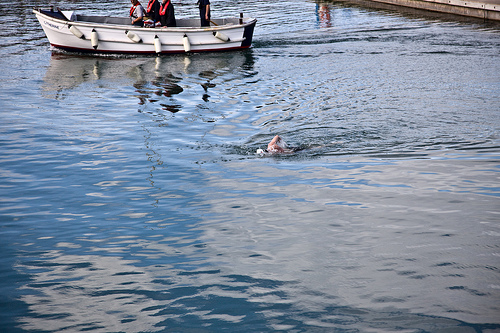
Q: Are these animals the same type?
A: Yes, all the animals are zebras.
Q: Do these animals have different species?
A: No, all the animals are zebras.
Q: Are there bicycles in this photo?
A: No, there are no bicycles.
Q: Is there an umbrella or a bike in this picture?
A: No, there are no bikes or umbrellas.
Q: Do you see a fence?
A: No, there are no fences.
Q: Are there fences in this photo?
A: No, there are no fences.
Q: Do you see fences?
A: No, there are no fences.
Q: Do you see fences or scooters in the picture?
A: No, there are no fences or scooters.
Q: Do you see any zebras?
A: Yes, there are zebras.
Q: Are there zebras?
A: Yes, there are zebras.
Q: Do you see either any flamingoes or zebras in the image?
A: Yes, there are zebras.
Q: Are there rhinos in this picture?
A: No, there are no rhinos.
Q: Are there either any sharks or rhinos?
A: No, there are no rhinos or sharks.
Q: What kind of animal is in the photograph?
A: The animal is zebras.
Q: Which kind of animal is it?
A: The animals are zebras.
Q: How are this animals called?
A: These are zebras.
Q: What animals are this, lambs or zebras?
A: These are zebras.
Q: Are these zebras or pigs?
A: These are zebras.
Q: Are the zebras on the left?
A: Yes, the zebras are on the left of the image.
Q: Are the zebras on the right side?
A: No, the zebras are on the left of the image.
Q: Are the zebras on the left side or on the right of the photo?
A: The zebras are on the left of the image.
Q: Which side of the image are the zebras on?
A: The zebras are on the left of the image.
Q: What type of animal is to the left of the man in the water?
A: The animals are zebras.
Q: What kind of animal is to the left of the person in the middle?
A: The animals are zebras.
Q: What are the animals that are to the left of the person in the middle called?
A: The animals are zebras.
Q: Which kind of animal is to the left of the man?
A: The animals are zebras.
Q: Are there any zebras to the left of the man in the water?
A: Yes, there are zebras to the left of the man.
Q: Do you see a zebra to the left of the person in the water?
A: Yes, there are zebras to the left of the man.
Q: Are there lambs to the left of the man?
A: No, there are zebras to the left of the man.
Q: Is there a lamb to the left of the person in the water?
A: No, there are zebras to the left of the man.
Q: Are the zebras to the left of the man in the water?
A: Yes, the zebras are to the left of the man.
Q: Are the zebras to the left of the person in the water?
A: Yes, the zebras are to the left of the man.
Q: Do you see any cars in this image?
A: No, there are no cars.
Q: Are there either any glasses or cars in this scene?
A: No, there are no cars or glasses.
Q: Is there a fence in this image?
A: No, there are no fences.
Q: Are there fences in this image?
A: No, there are no fences.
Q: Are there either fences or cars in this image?
A: No, there are no fences or cars.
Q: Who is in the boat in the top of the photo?
A: The people are in the boat.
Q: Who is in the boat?
A: The people are in the boat.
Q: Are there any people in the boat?
A: Yes, there are people in the boat.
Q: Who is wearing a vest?
A: The people are wearing a vest.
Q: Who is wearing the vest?
A: The people are wearing a vest.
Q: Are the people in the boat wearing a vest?
A: Yes, the people are wearing a vest.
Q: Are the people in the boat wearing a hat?
A: No, the people are wearing a vest.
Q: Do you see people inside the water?
A: Yes, there are people inside the water.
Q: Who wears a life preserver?
A: The people wear a life preserver.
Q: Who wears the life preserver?
A: The people wear a life preserver.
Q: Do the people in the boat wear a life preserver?
A: Yes, the people wear a life preserver.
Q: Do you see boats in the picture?
A: Yes, there is a boat.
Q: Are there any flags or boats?
A: Yes, there is a boat.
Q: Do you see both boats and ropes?
A: No, there is a boat but no ropes.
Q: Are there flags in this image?
A: No, there are no flags.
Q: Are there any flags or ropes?
A: No, there are no flags or ropes.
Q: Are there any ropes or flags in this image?
A: No, there are no flags or ropes.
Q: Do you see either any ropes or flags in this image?
A: No, there are no flags or ropes.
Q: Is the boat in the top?
A: Yes, the boat is in the top of the image.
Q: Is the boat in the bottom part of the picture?
A: No, the boat is in the top of the image.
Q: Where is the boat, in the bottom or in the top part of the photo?
A: The boat is in the top of the image.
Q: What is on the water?
A: The boat is on the water.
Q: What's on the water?
A: The boat is on the water.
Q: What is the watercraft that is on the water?
A: The watercraft is a boat.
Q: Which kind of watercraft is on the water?
A: The watercraft is a boat.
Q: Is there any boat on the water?
A: Yes, there is a boat on the water.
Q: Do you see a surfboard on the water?
A: No, there is a boat on the water.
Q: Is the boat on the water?
A: Yes, the boat is on the water.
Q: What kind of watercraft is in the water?
A: The watercraft is a boat.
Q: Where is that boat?
A: The boat is in the water.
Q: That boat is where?
A: The boat is in the water.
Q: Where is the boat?
A: The boat is in the water.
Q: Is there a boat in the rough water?
A: Yes, there is a boat in the water.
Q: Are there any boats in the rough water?
A: Yes, there is a boat in the water.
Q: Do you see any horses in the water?
A: No, there is a boat in the water.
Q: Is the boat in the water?
A: Yes, the boat is in the water.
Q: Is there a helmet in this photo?
A: No, there are no helmets.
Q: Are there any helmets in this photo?
A: No, there are no helmets.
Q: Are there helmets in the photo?
A: No, there are no helmets.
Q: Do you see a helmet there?
A: No, there are no helmets.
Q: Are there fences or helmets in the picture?
A: No, there are no helmets or fences.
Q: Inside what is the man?
A: The man is inside the water.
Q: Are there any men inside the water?
A: Yes, there is a man inside the water.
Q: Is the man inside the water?
A: Yes, the man is inside the water.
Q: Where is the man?
A: The man is in the water.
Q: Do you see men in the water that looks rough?
A: Yes, there is a man in the water.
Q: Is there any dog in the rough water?
A: No, there is a man in the water.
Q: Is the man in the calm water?
A: Yes, the man is in the water.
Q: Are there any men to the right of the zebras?
A: Yes, there is a man to the right of the zebras.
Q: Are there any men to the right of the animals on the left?
A: Yes, there is a man to the right of the zebras.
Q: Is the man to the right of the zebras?
A: Yes, the man is to the right of the zebras.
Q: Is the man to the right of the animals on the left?
A: Yes, the man is to the right of the zebras.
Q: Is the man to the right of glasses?
A: No, the man is to the right of the zebras.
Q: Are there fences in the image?
A: No, there are no fences.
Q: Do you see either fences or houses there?
A: No, there are no fences or houses.